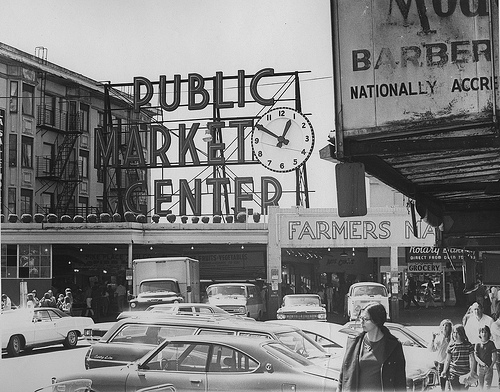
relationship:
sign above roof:
[88, 73, 298, 220] [20, 210, 275, 243]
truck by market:
[130, 258, 198, 300] [4, 216, 285, 309]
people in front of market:
[3, 288, 75, 318] [1, 67, 316, 330]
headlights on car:
[274, 311, 286, 318] [52, 333, 344, 390]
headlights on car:
[318, 311, 328, 320] [344, 279, 391, 321]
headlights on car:
[131, 302, 136, 308] [272, 292, 331, 322]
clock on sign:
[236, 86, 336, 178] [88, 73, 298, 220]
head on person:
[358, 300, 388, 333] [342, 294, 404, 383]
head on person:
[358, 300, 388, 333] [332, 301, 406, 390]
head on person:
[438, 315, 451, 336] [429, 319, 457, 389]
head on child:
[470, 300, 483, 318] [474, 323, 495, 390]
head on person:
[118, 279, 124, 285] [113, 281, 128, 307]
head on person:
[325, 279, 337, 291] [331, 279, 346, 313]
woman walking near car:
[333, 300, 410, 390] [176, 331, 321, 382]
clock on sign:
[251, 106, 315, 171] [88, 73, 298, 220]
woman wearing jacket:
[333, 300, 410, 390] [339, 328, 408, 388]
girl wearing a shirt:
[438, 317, 473, 390] [446, 340, 473, 371]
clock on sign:
[251, 106, 315, 171] [88, 55, 321, 220]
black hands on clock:
[254, 116, 293, 146] [251, 106, 315, 171]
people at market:
[331, 292, 499, 389] [329, 2, 499, 226]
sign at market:
[280, 213, 437, 243] [6, 184, 448, 316]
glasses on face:
[356, 313, 371, 323] [358, 306, 377, 334]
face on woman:
[358, 306, 377, 334] [333, 300, 410, 390]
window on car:
[208, 345, 259, 367] [51, 330, 336, 386]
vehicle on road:
[48, 332, 341, 389] [0, 309, 497, 390]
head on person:
[359, 301, 386, 333] [338, 300, 408, 391]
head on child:
[439, 316, 453, 333] [432, 317, 452, 389]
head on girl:
[451, 323, 472, 348] [440, 317, 471, 390]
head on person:
[63, 296, 71, 303] [61, 296, 71, 315]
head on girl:
[359, 301, 386, 333] [440, 317, 471, 390]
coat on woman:
[339, 329, 409, 389] [333, 300, 410, 390]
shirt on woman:
[356, 329, 385, 389] [333, 300, 410, 390]